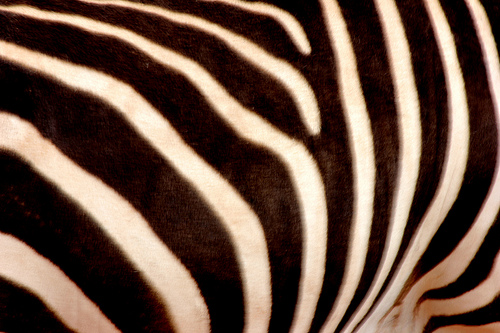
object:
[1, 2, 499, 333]
black and white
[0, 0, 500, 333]
zebra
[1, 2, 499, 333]
pattern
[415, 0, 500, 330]
stripes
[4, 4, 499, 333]
side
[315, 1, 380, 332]
white stripe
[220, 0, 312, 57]
stripe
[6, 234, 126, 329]
stripe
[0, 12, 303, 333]
stripes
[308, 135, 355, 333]
stripes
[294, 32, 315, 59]
end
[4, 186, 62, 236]
spots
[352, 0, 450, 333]
stripe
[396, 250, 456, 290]
end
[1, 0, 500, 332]
fur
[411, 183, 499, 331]
part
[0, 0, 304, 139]
stripes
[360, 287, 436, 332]
stripes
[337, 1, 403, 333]
black stripe